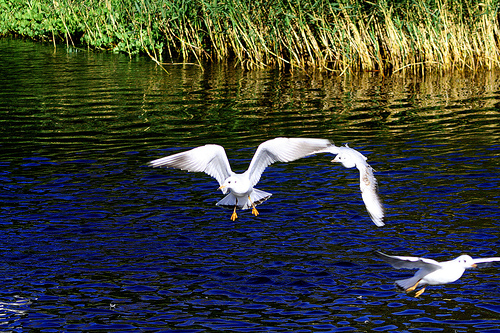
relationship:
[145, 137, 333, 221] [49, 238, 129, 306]
bird over water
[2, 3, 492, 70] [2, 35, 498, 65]
grass on shore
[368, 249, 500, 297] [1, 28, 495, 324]
bird flying over water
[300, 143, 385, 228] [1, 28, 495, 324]
bird flying over water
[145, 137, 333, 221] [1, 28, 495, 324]
bird flying over water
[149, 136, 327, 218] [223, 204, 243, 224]
bird has leg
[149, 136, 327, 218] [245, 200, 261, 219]
bird has leg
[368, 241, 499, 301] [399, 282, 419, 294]
bird has leg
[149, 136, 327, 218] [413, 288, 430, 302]
bird has leg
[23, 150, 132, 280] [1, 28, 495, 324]
dark spot in water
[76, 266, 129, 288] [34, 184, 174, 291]
dark spot in water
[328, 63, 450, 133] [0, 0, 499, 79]
water reflecting grass